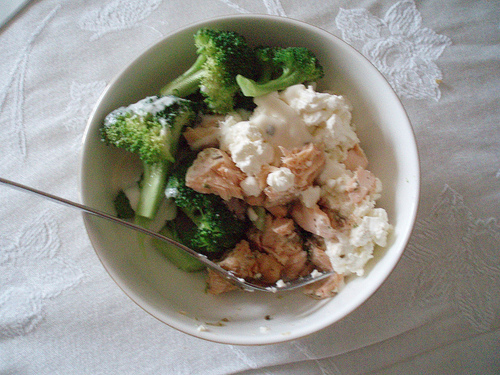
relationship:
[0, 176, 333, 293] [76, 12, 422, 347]
fork in bowl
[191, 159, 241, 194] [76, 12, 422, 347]
chicken in bowl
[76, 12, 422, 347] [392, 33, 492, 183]
bowl on table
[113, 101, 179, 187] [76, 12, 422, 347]
broccoli in bowl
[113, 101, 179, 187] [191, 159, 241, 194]
broccoli near chicken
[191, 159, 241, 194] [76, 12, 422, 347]
chicken near bowl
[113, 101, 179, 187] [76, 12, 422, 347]
broccoli on bowl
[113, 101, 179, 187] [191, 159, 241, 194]
broccoli in chicken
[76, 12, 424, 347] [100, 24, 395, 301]
bowl containing food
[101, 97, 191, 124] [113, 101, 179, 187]
dressing drizzled on broccoli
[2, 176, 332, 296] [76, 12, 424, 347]
fork lying in bowl